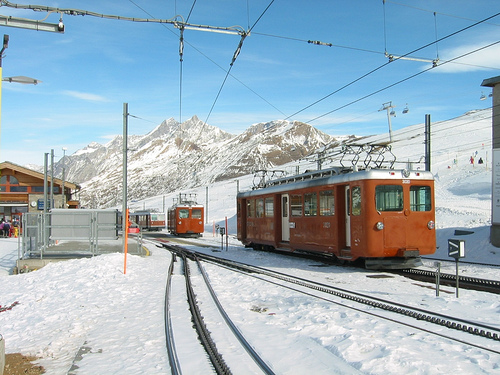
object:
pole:
[119, 209, 130, 274]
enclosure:
[15, 208, 128, 271]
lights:
[375, 221, 385, 232]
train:
[233, 162, 438, 272]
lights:
[178, 220, 183, 224]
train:
[167, 192, 205, 239]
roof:
[0, 159, 81, 193]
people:
[13, 216, 20, 237]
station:
[0, 157, 81, 252]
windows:
[0, 175, 58, 194]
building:
[0, 160, 82, 240]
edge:
[166, 342, 185, 375]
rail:
[153, 234, 500, 374]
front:
[351, 170, 440, 256]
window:
[377, 180, 407, 215]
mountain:
[45, 110, 500, 253]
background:
[0, 0, 499, 300]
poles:
[42, 151, 51, 249]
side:
[0, 12, 53, 375]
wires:
[0, 0, 500, 140]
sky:
[0, 2, 495, 164]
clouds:
[419, 30, 494, 80]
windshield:
[409, 184, 432, 213]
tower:
[480, 72, 499, 248]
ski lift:
[0, 2, 500, 87]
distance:
[0, 76, 500, 264]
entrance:
[330, 180, 361, 261]